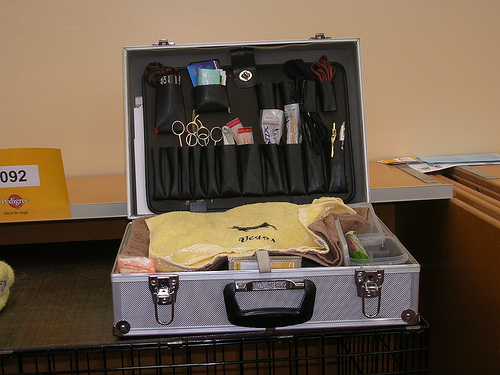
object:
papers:
[377, 153, 500, 174]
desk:
[0, 160, 500, 373]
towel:
[144, 197, 356, 269]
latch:
[147, 274, 180, 326]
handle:
[223, 279, 317, 329]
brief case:
[107, 33, 421, 340]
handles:
[172, 115, 223, 147]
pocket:
[254, 79, 338, 112]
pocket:
[154, 83, 187, 134]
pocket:
[193, 84, 232, 114]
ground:
[447, 166, 500, 375]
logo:
[227, 221, 277, 242]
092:
[0, 170, 27, 183]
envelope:
[0, 147, 72, 223]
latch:
[308, 33, 332, 40]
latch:
[151, 38, 175, 46]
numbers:
[1, 170, 27, 183]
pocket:
[150, 140, 350, 201]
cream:
[261, 109, 284, 146]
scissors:
[191, 110, 196, 134]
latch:
[354, 268, 385, 318]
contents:
[118, 196, 378, 272]